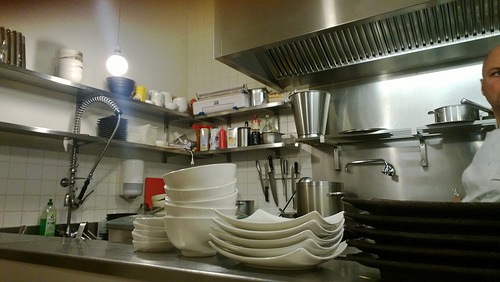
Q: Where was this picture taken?
A: Kitchen.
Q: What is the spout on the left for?
A: Sink.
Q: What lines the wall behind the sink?
A: Shelves.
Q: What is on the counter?
A: Bowls and plates.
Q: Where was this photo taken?
A: In a restaurant kitchen.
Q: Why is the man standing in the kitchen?
A: To do the dishes.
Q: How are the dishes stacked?
A: Neatly.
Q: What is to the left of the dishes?
A: A sink.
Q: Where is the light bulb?
A: Above the sink.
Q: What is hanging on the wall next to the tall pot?
A: Knives and other cooking utensils.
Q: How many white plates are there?
A: Five.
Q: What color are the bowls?
A: White.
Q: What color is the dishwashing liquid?
A: Green.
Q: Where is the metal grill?
A: Toward the top, right hand side of the photo.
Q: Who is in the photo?
A: A man.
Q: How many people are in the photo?
A: One.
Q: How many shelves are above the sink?
A: Two.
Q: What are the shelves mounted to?
A: The wall.